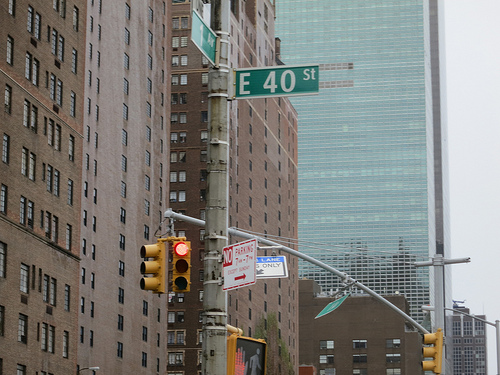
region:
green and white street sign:
[184, 29, 342, 124]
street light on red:
[118, 193, 223, 312]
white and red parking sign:
[210, 231, 258, 294]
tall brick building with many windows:
[25, 22, 327, 352]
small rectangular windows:
[12, 80, 154, 281]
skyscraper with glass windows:
[252, 10, 461, 348]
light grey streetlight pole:
[149, 178, 430, 358]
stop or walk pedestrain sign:
[211, 317, 275, 373]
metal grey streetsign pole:
[174, 35, 262, 369]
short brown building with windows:
[299, 264, 426, 368]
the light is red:
[173, 240, 188, 257]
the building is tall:
[318, 62, 438, 289]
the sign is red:
[215, 240, 258, 292]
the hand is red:
[235, 348, 245, 373]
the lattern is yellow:
[122, 234, 200, 310]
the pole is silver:
[415, 249, 462, 320]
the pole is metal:
[406, 258, 466, 321]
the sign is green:
[233, 63, 325, 103]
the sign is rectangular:
[215, 234, 257, 291]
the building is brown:
[95, 109, 135, 362]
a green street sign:
[182, 34, 475, 161]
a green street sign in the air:
[178, 22, 386, 145]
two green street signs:
[144, 10, 398, 141]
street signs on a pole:
[164, 10, 383, 128]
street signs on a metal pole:
[132, 3, 414, 155]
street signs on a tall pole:
[154, 11, 372, 113]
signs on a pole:
[144, 3, 409, 156]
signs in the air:
[151, 0, 428, 114]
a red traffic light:
[79, 175, 263, 345]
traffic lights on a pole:
[76, 157, 281, 314]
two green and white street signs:
[163, 7, 357, 110]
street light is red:
[171, 226, 205, 300]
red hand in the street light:
[220, 348, 244, 373]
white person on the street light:
[250, 344, 265, 373]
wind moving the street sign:
[297, 260, 387, 339]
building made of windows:
[332, 96, 437, 258]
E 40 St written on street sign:
[224, 66, 344, 112]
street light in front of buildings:
[75, 347, 125, 373]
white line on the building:
[234, 90, 319, 175]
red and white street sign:
[208, 237, 267, 292]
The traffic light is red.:
[160, 230, 202, 262]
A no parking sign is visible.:
[202, 232, 276, 300]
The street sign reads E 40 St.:
[212, 55, 357, 109]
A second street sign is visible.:
[174, 12, 238, 67]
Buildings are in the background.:
[0, 2, 448, 373]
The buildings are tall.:
[1, 2, 450, 372]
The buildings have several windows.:
[0, 2, 447, 373]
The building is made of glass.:
[257, 2, 447, 298]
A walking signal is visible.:
[221, 319, 282, 374]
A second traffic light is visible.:
[413, 317, 456, 373]